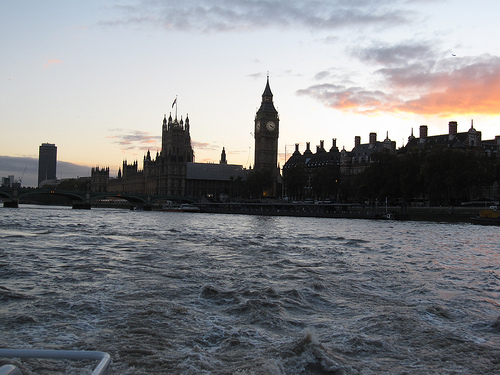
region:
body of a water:
[28, 297, 85, 324]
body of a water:
[131, 315, 173, 343]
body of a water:
[208, 312, 271, 364]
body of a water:
[325, 328, 375, 370]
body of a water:
[400, 294, 460, 348]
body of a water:
[289, 255, 341, 295]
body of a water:
[214, 218, 266, 258]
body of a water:
[145, 212, 191, 247]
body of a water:
[98, 214, 145, 244]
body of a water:
[50, 220, 98, 256]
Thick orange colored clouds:
[325, 52, 498, 123]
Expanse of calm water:
[0, 205, 498, 374]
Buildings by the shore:
[0, 71, 497, 228]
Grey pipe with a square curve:
[0, 343, 112, 373]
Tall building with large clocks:
[250, 65, 281, 198]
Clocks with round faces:
[251, 117, 276, 133]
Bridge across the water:
[0, 184, 206, 216]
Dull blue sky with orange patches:
[0, 0, 499, 170]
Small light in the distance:
[331, 176, 341, 186]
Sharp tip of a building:
[260, 66, 273, 99]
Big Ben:
[245, 77, 280, 190]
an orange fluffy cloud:
[372, 60, 497, 135]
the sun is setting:
[357, 46, 497, 143]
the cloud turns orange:
[362, 45, 485, 122]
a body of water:
[5, 218, 437, 353]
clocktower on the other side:
[229, 81, 274, 167]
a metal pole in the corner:
[9, 333, 101, 370]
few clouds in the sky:
[61, 2, 472, 148]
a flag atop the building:
[165, 78, 192, 122]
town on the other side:
[47, 118, 474, 244]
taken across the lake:
[29, 129, 475, 270]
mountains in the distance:
[15, 149, 100, 194]